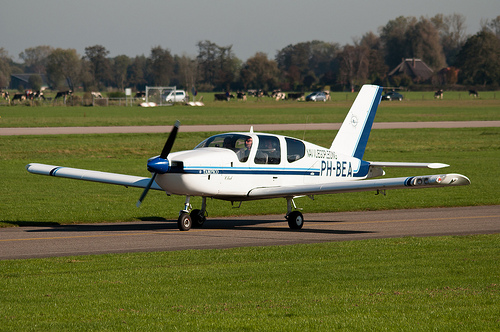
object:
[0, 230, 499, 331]
grass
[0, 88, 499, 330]
field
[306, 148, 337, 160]
writing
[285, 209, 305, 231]
wheel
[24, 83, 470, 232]
airplane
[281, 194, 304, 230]
landing gear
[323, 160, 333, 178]
letters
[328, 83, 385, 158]
tail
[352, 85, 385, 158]
stripe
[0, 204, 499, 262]
asphalt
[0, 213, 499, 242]
stripe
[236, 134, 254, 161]
man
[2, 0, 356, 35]
blue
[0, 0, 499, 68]
sky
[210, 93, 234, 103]
animals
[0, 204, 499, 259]
surface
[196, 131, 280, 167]
cockpit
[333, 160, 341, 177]
letters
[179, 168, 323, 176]
stripes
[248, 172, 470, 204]
wing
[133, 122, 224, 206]
front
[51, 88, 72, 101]
cows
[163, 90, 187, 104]
car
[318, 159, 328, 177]
letters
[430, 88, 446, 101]
cows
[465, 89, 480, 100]
cows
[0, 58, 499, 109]
farm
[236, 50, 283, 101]
trees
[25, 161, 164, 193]
wing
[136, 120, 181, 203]
propeller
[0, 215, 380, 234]
shadow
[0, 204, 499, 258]
runway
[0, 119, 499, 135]
runway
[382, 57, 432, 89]
building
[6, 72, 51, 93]
building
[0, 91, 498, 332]
ground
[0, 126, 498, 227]
grass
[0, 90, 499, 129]
grass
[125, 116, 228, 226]
part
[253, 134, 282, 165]
windows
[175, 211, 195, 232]
wheel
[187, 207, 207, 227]
wheel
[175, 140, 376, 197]
side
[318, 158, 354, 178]
writing